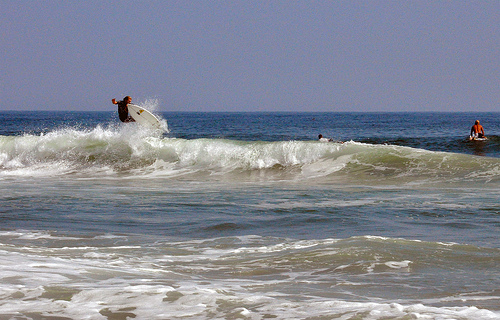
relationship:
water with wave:
[0, 109, 499, 319] [0, 116, 499, 188]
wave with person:
[0, 116, 499, 188] [105, 93, 130, 123]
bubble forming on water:
[1, 245, 389, 315] [116, 139, 410, 310]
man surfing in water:
[468, 118, 488, 141] [0, 109, 499, 319]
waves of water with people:
[233, 215, 399, 315] [96, 82, 491, 141]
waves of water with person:
[0, 228, 499, 319] [456, 108, 496, 145]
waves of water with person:
[0, 228, 499, 319] [103, 81, 140, 129]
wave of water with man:
[0, 116, 499, 188] [468, 118, 488, 141]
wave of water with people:
[0, 116, 499, 188] [38, 65, 493, 170]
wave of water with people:
[0, 116, 499, 188] [442, 111, 486, 152]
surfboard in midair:
[125, 99, 167, 134] [138, 50, 174, 170]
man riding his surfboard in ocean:
[468, 118, 487, 139] [15, 131, 497, 313]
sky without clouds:
[0, 2, 500, 114] [224, 53, 338, 123]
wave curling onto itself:
[0, 116, 499, 188] [154, 148, 266, 231]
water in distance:
[0, 108, 497, 318] [113, 54, 413, 305]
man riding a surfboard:
[110, 95, 132, 120] [125, 102, 161, 129]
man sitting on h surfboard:
[468, 118, 488, 141] [138, 119, 168, 226]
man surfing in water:
[110, 95, 133, 124] [0, 109, 499, 319]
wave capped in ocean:
[0, 116, 499, 188] [14, 107, 496, 288]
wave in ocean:
[0, 116, 499, 188] [211, 119, 461, 286]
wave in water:
[0, 116, 499, 188] [0, 109, 499, 319]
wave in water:
[0, 125, 493, 177] [0, 109, 499, 319]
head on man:
[121, 92, 131, 103] [108, 93, 137, 125]